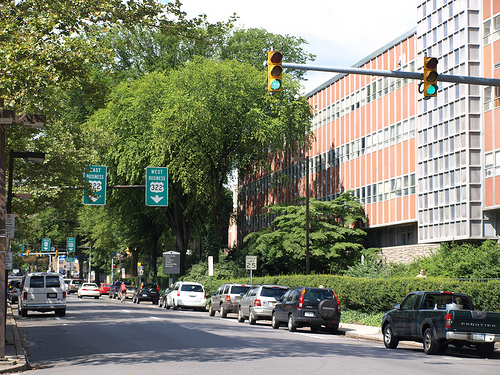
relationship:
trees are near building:
[83, 56, 316, 275] [236, 0, 497, 265]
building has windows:
[236, 0, 497, 265] [371, 185, 378, 195]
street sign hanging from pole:
[267, 51, 289, 96] [266, 50, 497, 98]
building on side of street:
[236, 0, 497, 265] [9, 290, 499, 374]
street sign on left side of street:
[267, 51, 289, 96] [9, 290, 499, 374]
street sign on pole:
[267, 51, 289, 96] [266, 50, 497, 98]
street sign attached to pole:
[267, 51, 289, 96] [266, 50, 497, 98]